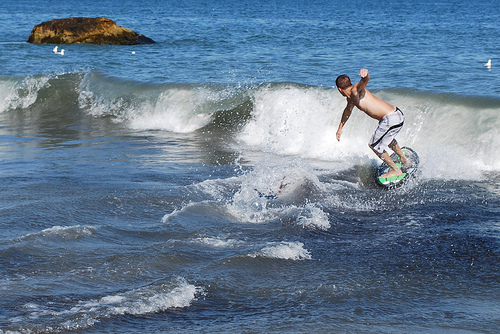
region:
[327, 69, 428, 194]
man surfing in the ocean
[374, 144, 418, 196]
top of the surfboard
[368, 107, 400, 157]
white and black boardshorts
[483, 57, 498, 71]
white bird in the ocean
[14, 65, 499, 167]
wave the surfer is riding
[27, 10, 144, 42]
large rock in the ocean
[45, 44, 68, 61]
two birds in front of the rock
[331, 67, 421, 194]
Man riding a surfboard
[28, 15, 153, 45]
big rock jutting out from water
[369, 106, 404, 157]
White swim trunks with black stripe on man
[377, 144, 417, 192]
Man's feet on the surfboard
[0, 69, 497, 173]
Crest of breaking wave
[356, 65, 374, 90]
Man's left arm extended behind hime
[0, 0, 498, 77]
Calm water behind the wave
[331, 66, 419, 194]
Man surfing in the water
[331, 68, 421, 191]
Man standing on a surfboard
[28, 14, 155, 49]
Brown rock in the water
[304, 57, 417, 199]
man on surf board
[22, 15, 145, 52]
brown rock in water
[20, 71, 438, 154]
large wave cresting by surfer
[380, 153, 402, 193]
neon green on board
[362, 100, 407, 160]
white and black surf shorts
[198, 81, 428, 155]
large cresting wave by surfer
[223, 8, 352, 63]
dark blue water behind wave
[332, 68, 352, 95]
short dark hair on man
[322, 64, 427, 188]
a man on a surfboard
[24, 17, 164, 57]
a small rock that sticks up in the ocean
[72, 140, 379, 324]
white caps in the water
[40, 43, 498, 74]
birds flying above the surface of the water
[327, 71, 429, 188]
a boy plays in the water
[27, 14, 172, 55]
a rock formation sticks out of the sea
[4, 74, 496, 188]
a small wave dips down in the ocean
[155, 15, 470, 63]
calm ocean water in the daytime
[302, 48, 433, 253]
the boy is surfing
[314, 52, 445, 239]
the boy is surfing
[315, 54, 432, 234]
the boy is surfing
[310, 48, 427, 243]
the boy is surfing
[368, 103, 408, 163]
the shorts are gray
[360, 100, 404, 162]
the shorts are gray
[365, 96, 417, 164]
the shorts are gray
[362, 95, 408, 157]
the shorts are gray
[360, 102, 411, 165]
the shorts are gray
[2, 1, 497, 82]
surface of ocean water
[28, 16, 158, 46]
rock in ocean water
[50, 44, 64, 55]
seagulls floating on water